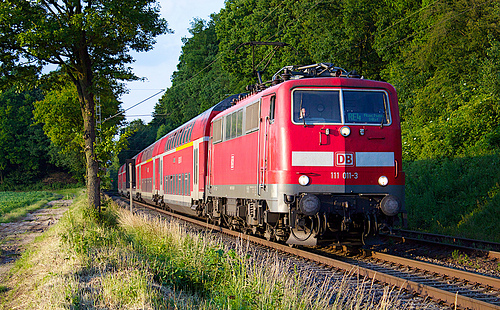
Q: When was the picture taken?
A: Daytime.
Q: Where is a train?
A: On a train track.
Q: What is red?
A: Train.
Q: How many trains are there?
A: One.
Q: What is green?
A: Trees.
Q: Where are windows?
A: On the train.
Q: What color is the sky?
A: Blue.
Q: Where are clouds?
A: In the sky.